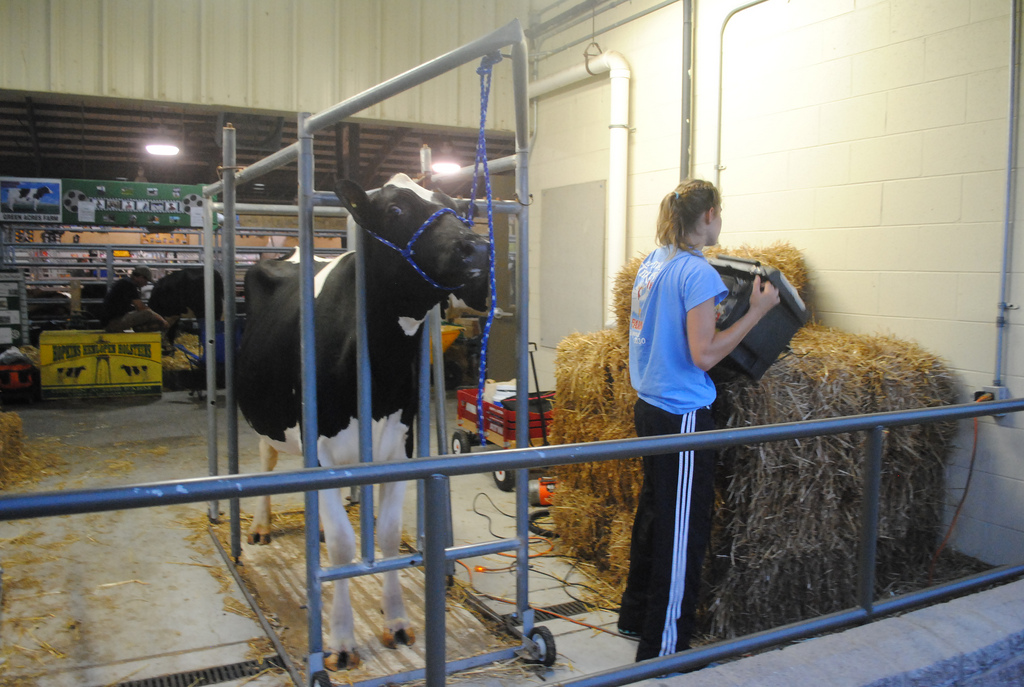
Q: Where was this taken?
A: Farm.